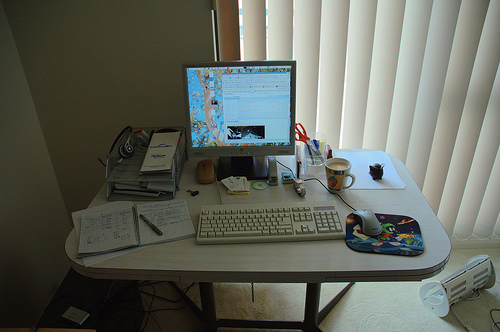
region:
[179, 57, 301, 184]
square flat screen computer monitor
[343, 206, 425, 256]
blue mouse pad with cartoons on it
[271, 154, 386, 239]
white and gray mouse with wire attached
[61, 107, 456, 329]
square white computer table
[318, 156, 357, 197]
white and yellow cup of coffee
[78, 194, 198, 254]
open notebook with writing on it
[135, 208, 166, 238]
black pen lying on notebook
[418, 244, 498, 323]
small white floor heater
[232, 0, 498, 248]
white blinds on large window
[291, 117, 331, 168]
scissors with orange handle in clear cup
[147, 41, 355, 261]
a computer on a table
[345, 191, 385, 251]
a wired silver mouse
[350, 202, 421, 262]
a mouse pad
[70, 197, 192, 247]
an opened notebook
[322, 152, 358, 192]
a cup of coffee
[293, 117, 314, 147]
a pair of red scissors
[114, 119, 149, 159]
headphones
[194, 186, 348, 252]
a wired keyboard on a table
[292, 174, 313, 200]
a silver watch on a table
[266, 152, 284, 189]
a silver stapler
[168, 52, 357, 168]
the monitor is on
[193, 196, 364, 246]
keyboard on the table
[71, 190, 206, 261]
the notebook is open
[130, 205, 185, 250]
pen on the notebook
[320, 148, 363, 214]
the mug is on the table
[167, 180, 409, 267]
the keyboard is white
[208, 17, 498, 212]
the blinds are closed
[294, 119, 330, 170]
the scissors are red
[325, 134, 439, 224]
the paper is white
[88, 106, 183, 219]
filing tray beside the monitor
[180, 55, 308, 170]
A FLAT SCREEN COMPUTER MONITOR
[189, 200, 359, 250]
A WHITE COMPUTER KEYBOARD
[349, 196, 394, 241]
A WHITE COMPUTER MOUSE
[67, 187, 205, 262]
AN OPEN NOTEBOOK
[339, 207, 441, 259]
A COMPUTER MOUSE PAD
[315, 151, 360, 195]
A COFFEE CUP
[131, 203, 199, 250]
A PEN ON A NOTEBOOK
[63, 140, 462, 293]
A WHITE TABLE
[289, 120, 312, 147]
A PAIR OF ORANGE SCISSORS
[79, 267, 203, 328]
COMPUTER CORDS ON THE FLOOR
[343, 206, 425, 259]
marvin the martian on a mousepad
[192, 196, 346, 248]
an older flat extended keyboard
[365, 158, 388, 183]
some sort of animal figurine disguised as a paperweight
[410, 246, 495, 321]
a tipped over heater or light on the floor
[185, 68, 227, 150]
a tree or, perhaps, a fractal as the monitor's background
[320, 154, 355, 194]
orangey coffee in a cup w/ a strawberry on it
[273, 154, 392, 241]
one wired mouse, black+silvertone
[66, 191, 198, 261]
a pen atop a notebook w/ notes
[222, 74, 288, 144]
an open window on the monitor with a small rectangular picture in it along w/ text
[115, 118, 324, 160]
an orange handled scissors &, on the other side, collapsible headphones